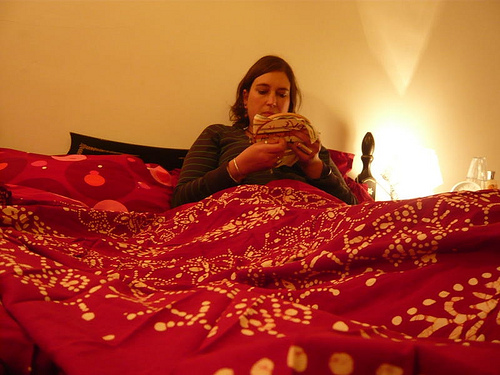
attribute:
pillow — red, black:
[0, 146, 178, 211]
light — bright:
[357, 117, 444, 201]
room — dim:
[2, 2, 499, 370]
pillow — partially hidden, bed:
[4, 151, 206, 215]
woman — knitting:
[155, 49, 362, 213]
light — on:
[376, 127, 450, 215]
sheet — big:
[1, 179, 498, 371]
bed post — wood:
[351, 126, 387, 194]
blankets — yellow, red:
[79, 169, 420, 370]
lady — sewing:
[181, 75, 381, 201]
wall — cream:
[4, 4, 497, 204]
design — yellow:
[212, 279, 322, 344]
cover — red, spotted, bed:
[1, 145, 485, 365]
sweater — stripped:
[165, 122, 352, 200]